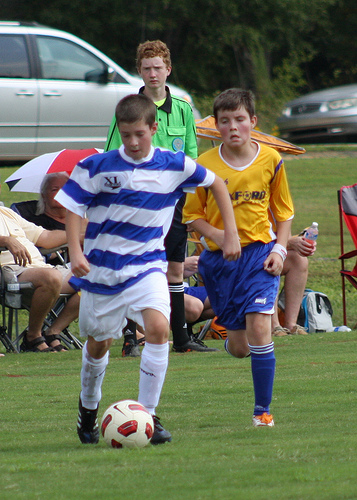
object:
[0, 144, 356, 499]
grass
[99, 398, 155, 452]
ball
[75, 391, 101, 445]
shoes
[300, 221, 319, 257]
bottle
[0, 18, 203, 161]
cars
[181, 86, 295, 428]
boys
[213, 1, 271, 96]
trees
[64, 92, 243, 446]
boy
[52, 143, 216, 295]
shirt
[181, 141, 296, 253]
jersey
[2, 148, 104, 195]
umbrella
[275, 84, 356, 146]
car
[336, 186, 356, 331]
chair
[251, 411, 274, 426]
shoe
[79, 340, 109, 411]
shin guards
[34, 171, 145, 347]
woman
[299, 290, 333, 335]
bag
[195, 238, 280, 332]
shorts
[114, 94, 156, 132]
hair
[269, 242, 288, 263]
wristband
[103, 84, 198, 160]
shirt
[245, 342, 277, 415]
shin guards